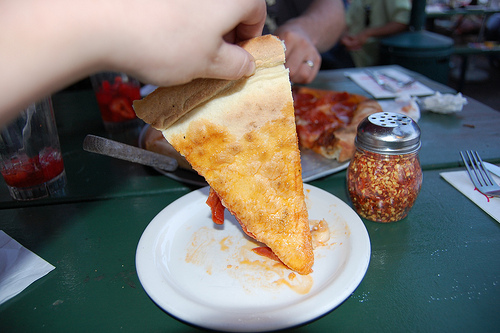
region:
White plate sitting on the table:
[135, 175, 371, 327]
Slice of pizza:
[131, 32, 318, 281]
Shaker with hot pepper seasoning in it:
[347, 108, 425, 225]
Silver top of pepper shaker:
[355, 107, 422, 154]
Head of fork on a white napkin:
[456, 145, 498, 200]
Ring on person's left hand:
[300, 47, 317, 73]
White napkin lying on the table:
[0, 223, 57, 311]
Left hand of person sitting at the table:
[275, 17, 326, 89]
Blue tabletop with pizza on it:
[1, 60, 496, 328]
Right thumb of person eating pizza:
[192, 29, 264, 84]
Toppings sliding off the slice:
[203, 183, 290, 273]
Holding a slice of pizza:
[117, 10, 323, 278]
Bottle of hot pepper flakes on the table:
[350, 108, 428, 225]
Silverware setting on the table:
[357, 64, 422, 94]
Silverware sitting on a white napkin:
[341, 65, 439, 99]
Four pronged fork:
[456, 148, 498, 205]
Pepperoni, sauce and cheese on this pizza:
[291, 83, 371, 153]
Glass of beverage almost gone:
[3, 90, 78, 205]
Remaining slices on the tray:
[291, 77, 386, 183]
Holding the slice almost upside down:
[118, 30, 330, 276]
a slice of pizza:
[80, 28, 461, 328]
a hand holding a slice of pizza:
[126, 9, 443, 329]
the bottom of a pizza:
[60, 16, 390, 330]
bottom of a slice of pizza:
[101, 1, 421, 330]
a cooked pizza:
[122, 27, 376, 294]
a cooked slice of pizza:
[69, 23, 426, 328]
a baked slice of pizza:
[67, 15, 403, 332]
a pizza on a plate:
[67, 18, 492, 314]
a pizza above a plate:
[116, 31, 444, 329]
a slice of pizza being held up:
[71, 33, 366, 328]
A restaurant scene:
[1, 0, 496, 327]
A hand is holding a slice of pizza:
[0, 0, 320, 274]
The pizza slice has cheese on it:
[132, 34, 313, 278]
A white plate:
[133, 177, 370, 330]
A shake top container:
[346, 111, 423, 224]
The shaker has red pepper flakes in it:
[346, 109, 424, 224]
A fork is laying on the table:
[457, 145, 498, 200]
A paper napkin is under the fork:
[439, 147, 498, 223]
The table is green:
[0, 63, 498, 331]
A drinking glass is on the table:
[0, 93, 69, 203]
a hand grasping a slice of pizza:
[65, 0, 290, 101]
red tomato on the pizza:
[200, 194, 230, 221]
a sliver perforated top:
[357, 112, 426, 144]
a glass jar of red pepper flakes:
[344, 157, 426, 220]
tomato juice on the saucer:
[224, 244, 253, 268]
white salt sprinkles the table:
[397, 237, 473, 306]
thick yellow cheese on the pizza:
[229, 145, 291, 202]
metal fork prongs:
[461, 150, 493, 199]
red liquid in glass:
[6, 145, 63, 184]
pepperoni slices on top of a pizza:
[301, 87, 339, 133]